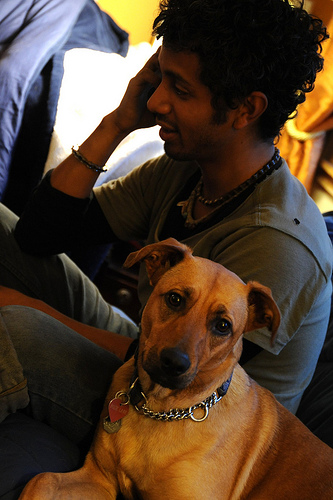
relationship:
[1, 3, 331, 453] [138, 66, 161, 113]
guy talking on phone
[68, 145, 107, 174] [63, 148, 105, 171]
bracelet on wrist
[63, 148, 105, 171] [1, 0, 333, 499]
wrist on guy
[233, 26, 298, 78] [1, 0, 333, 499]
hair on guy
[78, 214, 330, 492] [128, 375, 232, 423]
dog wearing collar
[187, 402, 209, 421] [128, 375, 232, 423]
loop on collar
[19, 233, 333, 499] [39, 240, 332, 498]
dog has nose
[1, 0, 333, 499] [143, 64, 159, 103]
guy talking on phone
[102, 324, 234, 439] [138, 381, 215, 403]
collar on neck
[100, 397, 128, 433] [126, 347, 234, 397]
dog tags on neck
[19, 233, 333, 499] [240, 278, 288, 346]
dog has ear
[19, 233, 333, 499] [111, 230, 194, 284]
dog has ear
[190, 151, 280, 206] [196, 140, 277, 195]
necklace on neck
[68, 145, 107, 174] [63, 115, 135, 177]
bracelet on wrist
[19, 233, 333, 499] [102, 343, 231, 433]
dog wearing collar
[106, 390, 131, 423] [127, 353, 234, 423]
heart on collar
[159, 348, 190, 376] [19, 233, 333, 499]
nose on dog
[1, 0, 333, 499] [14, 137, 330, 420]
guy wearing shirt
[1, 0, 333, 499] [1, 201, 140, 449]
guy wearing jeans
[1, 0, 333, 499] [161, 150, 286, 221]
guy wearing necklace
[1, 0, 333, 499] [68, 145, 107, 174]
guy wearing bracelet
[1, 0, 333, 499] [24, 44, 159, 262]
guy holding up arm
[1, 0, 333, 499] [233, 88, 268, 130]
guy with ear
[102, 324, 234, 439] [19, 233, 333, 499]
collar around dog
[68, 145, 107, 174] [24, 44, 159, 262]
bracelet on arm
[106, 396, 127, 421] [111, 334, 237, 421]
charm on collar